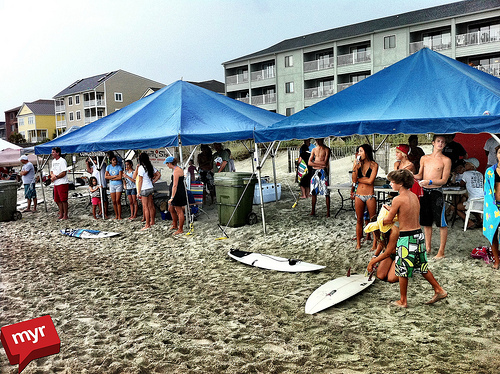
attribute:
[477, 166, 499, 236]
towel — blue , yellow 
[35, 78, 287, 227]
tent — blue, large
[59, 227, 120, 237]
surfboard — blue, white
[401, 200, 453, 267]
trunks — multi-colored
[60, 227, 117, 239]
surfboard — White, Blue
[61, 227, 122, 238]
surfboard — white, black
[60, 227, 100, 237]
towel — blue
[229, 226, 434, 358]
surfboard — White, Black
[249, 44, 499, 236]
tent — large, blue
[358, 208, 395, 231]
hat — yellow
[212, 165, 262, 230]
garbage_can — Large, Green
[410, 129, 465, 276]
man — black and blue 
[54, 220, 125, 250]
surfboard — white 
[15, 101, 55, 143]
house — yellow, beach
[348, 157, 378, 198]
suit — Black, White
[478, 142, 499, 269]
person — light aqua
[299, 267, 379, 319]
surfboard — white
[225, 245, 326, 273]
surfboard — Black, White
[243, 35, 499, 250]
tent — blue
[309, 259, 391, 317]
surfboard — upside down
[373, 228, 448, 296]
trunks — Green, yellow , white 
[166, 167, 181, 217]
bathing suit — black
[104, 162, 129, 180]
shirt — blue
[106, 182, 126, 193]
shorts — white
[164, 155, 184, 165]
cap — blue 